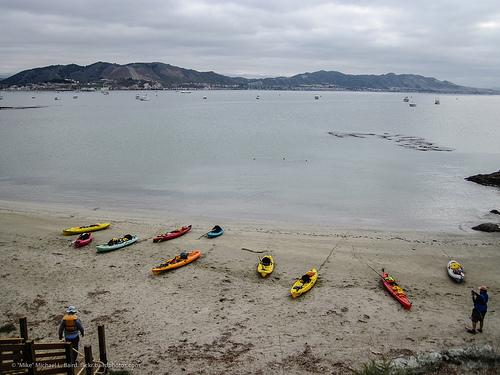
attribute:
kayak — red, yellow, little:
[288, 267, 324, 300]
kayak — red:
[379, 266, 414, 313]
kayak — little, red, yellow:
[151, 223, 193, 244]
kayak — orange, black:
[150, 249, 203, 275]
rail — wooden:
[2, 315, 110, 374]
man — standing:
[58, 304, 86, 361]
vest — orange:
[61, 313, 80, 332]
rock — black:
[471, 221, 499, 232]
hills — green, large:
[0, 59, 499, 88]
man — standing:
[467, 285, 490, 336]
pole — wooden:
[96, 320, 109, 363]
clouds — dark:
[0, 1, 499, 78]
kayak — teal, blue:
[206, 222, 225, 239]